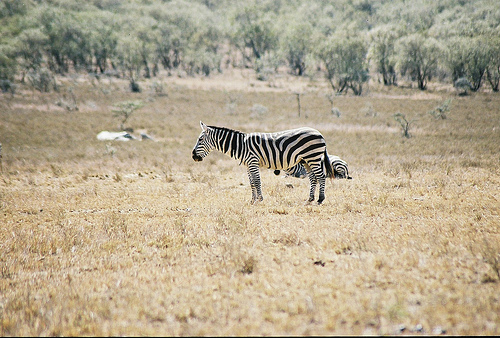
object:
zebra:
[191, 119, 336, 205]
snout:
[192, 152, 198, 160]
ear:
[200, 120, 206, 130]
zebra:
[273, 152, 352, 181]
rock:
[97, 130, 140, 143]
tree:
[366, 28, 402, 86]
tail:
[325, 150, 334, 180]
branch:
[249, 38, 261, 58]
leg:
[305, 157, 326, 200]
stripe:
[293, 142, 325, 163]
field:
[0, 69, 500, 338]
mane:
[209, 126, 246, 136]